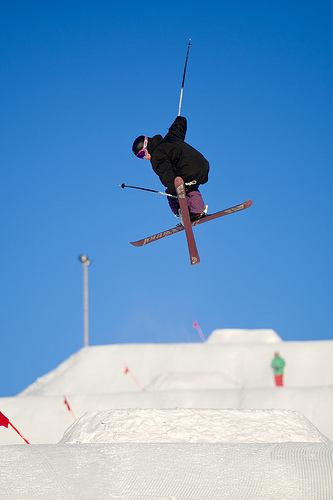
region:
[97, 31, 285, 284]
skier in the air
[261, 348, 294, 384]
a person in green and red clothing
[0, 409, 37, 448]
a red flag stuck in the snow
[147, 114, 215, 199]
a black coat on a person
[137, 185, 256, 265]
two skis in crossed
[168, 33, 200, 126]
ski pole in the air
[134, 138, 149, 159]
ski goggles on a person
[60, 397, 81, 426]
red flag stuck in the snow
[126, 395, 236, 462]
two white snow slopes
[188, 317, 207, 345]
red flag stuck in the snow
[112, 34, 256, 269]
a skier doing tricks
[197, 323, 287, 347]
a ski jump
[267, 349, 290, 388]
a person standing in the snow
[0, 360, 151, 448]
three red flags next to ramps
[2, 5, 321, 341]
a clear bright blue sky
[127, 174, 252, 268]
skis crossed in an X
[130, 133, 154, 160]
red ski goggles on face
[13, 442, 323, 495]
freshly groomed snow ramp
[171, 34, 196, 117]
a pole sticking straight up in the air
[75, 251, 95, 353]
a pole with lights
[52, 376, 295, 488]
flag is red and long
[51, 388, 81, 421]
flag is red and long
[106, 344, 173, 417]
flag is red and long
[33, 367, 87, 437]
flag is red and long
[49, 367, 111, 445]
flag is red and long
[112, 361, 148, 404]
flag is red and long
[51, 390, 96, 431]
flag is red and long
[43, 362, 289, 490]
snow is white and wavy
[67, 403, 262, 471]
snow is white and wavy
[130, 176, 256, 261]
The skis are maroon.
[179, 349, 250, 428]
Snow on the ground.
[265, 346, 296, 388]
Person standing in the snow.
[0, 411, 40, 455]
The flag is red.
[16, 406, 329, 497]
The steps are snow covered.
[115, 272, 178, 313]
The sky is blue.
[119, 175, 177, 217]
The ski stick is black and white.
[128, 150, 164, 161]
The skier is wearing goggles.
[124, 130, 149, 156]
The skier is wearing a helmet.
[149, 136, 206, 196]
The jacket is black.